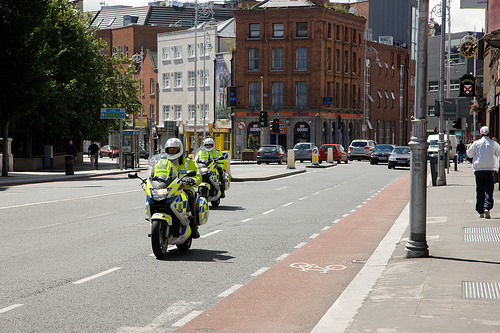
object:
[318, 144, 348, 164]
car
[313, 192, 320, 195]
line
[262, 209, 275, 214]
line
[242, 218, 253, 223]
line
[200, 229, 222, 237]
line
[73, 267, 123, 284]
line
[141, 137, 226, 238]
people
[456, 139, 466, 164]
person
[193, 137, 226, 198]
person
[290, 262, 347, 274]
indicator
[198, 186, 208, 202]
wheel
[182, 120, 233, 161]
storefront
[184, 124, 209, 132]
sign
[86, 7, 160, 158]
building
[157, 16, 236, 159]
building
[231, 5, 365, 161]
building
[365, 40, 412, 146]
building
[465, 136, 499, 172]
white jacket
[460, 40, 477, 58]
clock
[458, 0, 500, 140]
building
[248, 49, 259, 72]
window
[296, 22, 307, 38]
window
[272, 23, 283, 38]
window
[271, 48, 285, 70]
window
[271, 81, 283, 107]
window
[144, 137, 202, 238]
person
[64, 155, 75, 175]
trash can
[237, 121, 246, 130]
traffic sign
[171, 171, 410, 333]
bicycle lane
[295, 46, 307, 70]
window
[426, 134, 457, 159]
van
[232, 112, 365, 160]
store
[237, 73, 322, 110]
apartment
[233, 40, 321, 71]
apartment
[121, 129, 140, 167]
telephone booth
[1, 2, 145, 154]
tree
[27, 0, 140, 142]
leaves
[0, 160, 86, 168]
wall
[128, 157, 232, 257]
motorcycles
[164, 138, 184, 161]
helmet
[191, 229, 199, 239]
boots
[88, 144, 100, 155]
shirt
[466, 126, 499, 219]
person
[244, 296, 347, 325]
lane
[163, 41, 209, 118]
facade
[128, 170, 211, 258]
motorcycle